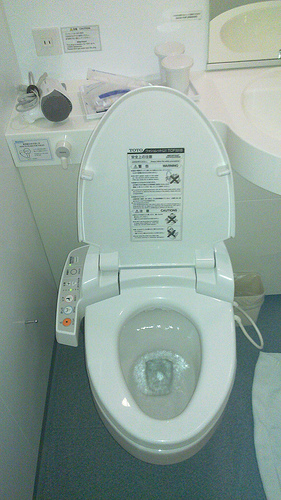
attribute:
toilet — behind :
[48, 87, 240, 465]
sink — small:
[230, 65, 280, 194]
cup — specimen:
[162, 54, 194, 95]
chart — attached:
[112, 138, 186, 241]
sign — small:
[61, 24, 103, 52]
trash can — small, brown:
[231, 269, 265, 329]